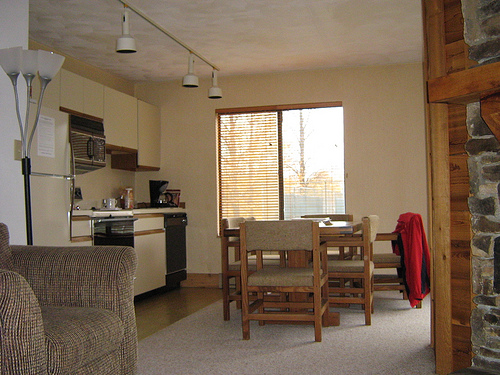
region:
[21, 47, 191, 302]
a kitchenette on one wall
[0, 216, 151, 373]
a soft chair in front of the kitchenette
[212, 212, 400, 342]
a table across the room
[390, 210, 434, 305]
a red jacket on the chair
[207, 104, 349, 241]
a window behind the table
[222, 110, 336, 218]
blinds on the window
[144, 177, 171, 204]
a coffeepot on the counter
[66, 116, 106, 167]
a microwave in the kitchenette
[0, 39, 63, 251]
a lamp behind the chair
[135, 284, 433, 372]
a carpet on the floor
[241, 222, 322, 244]
top back of beige chair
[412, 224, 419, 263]
red coat on chair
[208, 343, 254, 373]
grey carpet on floor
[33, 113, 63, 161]
white paper on fridge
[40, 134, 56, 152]
black lettering on paper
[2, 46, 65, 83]
light on top of pole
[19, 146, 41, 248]
pole holding light up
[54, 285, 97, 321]
stitched pattern on couch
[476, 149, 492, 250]
brick fire place in house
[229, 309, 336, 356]
bottom of back of chair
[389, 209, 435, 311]
Red jacket hanging from chair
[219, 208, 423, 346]
Table and chairs in the kitchen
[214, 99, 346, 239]
Window behind the table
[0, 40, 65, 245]
Floor lamp beside chair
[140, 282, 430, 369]
Grey rug on the floor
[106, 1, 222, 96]
Track lighting on the ceiling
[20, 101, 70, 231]
White refrigerator with note attached to it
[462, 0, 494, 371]
edge of stone fireplace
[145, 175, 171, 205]
Coffee maker on the counter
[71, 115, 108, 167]
Microwave over the stove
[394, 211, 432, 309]
a red coat hanging on chair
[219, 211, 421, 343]
a set of wooden chairs and table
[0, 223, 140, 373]
a beige and grey sofa chair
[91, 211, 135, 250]
a black oven door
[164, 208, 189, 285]
a black and metal dishwasher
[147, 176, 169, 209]
a black coffee maker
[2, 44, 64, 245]
a stand up lamp with three heads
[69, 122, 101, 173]
a stainless steel microwave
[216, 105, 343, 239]
a large window with brown blinds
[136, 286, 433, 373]
a grey rug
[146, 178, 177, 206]
A black coffee machine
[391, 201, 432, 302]
A red sweater sitting on a chair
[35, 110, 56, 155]
A paper with writing on the refrigerator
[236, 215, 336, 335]
A cushioned wooden chair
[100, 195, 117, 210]
A white cup on a white plate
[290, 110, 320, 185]
A tree with no leaves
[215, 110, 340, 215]
Two rectangular shaped windows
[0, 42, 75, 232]
A tall three bulb lamp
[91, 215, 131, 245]
A smooth black oven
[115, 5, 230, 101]
A row of white lights